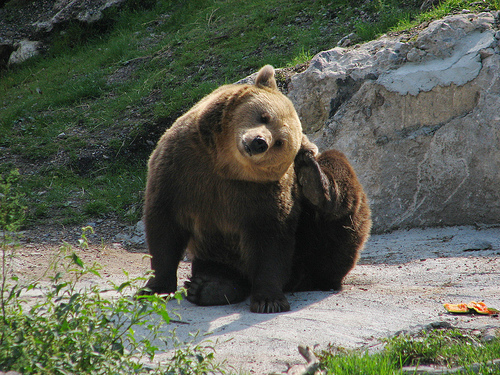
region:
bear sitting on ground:
[107, 41, 382, 319]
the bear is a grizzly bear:
[131, 30, 385, 320]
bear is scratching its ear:
[110, 52, 380, 319]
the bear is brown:
[108, 41, 373, 328]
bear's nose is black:
[241, 130, 275, 157]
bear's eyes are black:
[248, 103, 293, 164]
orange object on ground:
[417, 287, 498, 316]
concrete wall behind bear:
[256, 3, 496, 220]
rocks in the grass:
[0, 0, 140, 83]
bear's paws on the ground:
[133, 260, 300, 311]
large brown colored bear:
[135, 61, 370, 312]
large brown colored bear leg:
[136, 171, 187, 301]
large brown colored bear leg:
[242, 206, 297, 314]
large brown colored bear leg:
[297, 154, 369, 289]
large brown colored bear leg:
[184, 254, 246, 308]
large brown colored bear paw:
[135, 282, 181, 299]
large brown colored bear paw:
[181, 275, 246, 305]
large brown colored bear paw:
[247, 284, 292, 313]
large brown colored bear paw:
[296, 149, 333, 206]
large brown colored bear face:
[223, 82, 298, 177]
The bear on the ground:
[115, 59, 393, 329]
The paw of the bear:
[248, 284, 295, 319]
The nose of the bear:
[251, 130, 269, 155]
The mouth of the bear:
[235, 133, 258, 165]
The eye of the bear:
[273, 134, 285, 153]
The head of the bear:
[210, 58, 323, 183]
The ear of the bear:
[250, 53, 280, 85]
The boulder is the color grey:
[339, 35, 497, 237]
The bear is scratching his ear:
[288, 121, 350, 238]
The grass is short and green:
[28, 58, 140, 175]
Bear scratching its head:
[149, 45, 471, 367]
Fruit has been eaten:
[424, 279, 498, 327]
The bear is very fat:
[165, 60, 438, 374]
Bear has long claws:
[235, 252, 296, 309]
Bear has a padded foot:
[170, 244, 257, 319]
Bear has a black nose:
[242, 121, 277, 166]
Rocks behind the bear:
[347, 24, 488, 189]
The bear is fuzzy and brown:
[133, 85, 403, 349]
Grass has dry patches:
[40, 57, 165, 219]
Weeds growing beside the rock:
[16, 256, 139, 371]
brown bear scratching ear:
[135, 61, 369, 321]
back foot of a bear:
[296, 145, 349, 222]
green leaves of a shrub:
[3, 219, 174, 364]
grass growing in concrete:
[318, 342, 463, 374]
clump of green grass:
[307, 343, 399, 373]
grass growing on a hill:
[6, 27, 145, 140]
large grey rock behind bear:
[295, 9, 499, 232]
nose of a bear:
[247, 132, 270, 158]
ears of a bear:
[254, 62, 322, 162]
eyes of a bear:
[255, 106, 289, 155]